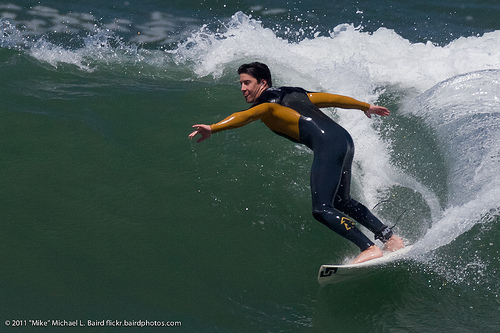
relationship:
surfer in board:
[188, 60, 415, 283] [315, 247, 411, 280]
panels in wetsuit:
[211, 102, 299, 137] [205, 84, 393, 244]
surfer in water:
[188, 60, 415, 283] [3, 3, 498, 329]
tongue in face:
[242, 93, 247, 98] [238, 72, 259, 102]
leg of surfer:
[313, 145, 380, 264] [185, 50, 422, 239]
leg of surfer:
[313, 145, 380, 264] [188, 60, 415, 283]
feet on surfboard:
[340, 231, 414, 256] [316, 235, 431, 284]